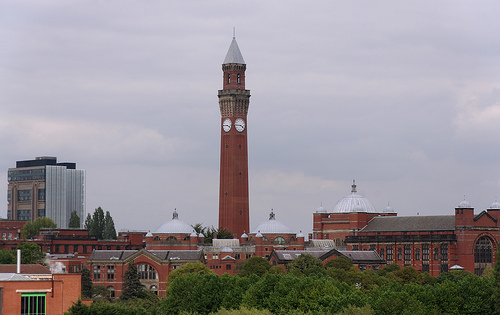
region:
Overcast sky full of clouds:
[0, 0, 499, 250]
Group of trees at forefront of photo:
[66, 248, 497, 314]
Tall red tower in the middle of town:
[203, 14, 265, 271]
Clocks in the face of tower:
[216, 112, 254, 139]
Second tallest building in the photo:
[0, 147, 95, 245]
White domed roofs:
[133, 178, 408, 243]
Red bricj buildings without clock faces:
[0, 198, 496, 313]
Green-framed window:
[16, 288, 51, 314]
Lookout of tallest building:
[219, 23, 249, 91]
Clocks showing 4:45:
[216, 113, 253, 138]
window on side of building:
[435, 243, 447, 261]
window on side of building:
[421, 243, 436, 266]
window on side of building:
[386, 246, 399, 264]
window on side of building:
[151, 267, 163, 280]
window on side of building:
[133, 265, 150, 282]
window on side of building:
[101, 265, 116, 278]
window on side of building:
[89, 261, 104, 278]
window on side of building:
[336, 240, 351, 246]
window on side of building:
[225, 263, 232, 273]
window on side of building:
[210, 262, 220, 270]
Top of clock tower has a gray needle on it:
[231, 24, 236, 36]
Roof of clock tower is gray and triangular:
[222, 38, 244, 64]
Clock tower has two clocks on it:
[221, 116, 247, 136]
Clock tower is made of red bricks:
[220, 132, 250, 237]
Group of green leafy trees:
[109, 261, 499, 313]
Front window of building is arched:
[473, 230, 497, 273]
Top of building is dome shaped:
[155, 209, 197, 234]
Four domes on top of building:
[314, 172, 395, 215]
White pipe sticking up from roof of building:
[15, 247, 22, 275]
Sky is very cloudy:
[2, 1, 498, 154]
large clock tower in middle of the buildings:
[213, 26, 253, 236]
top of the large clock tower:
[217, 24, 248, 89]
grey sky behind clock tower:
[3, 2, 498, 224]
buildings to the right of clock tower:
[250, 178, 498, 261]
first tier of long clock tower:
[215, 90, 250, 116]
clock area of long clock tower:
[219, 118, 247, 133]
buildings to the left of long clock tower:
[0, 207, 215, 314]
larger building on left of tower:
[6, 153, 88, 228]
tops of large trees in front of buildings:
[76, 259, 496, 314]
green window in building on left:
[19, 293, 44, 314]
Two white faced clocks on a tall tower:
[219, 116, 250, 134]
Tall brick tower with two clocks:
[215, 25, 257, 243]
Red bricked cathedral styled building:
[350, 198, 499, 278]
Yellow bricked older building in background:
[2, 155, 87, 228]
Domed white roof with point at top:
[306, 174, 396, 214]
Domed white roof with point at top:
[247, 206, 295, 233]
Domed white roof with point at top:
[152, 210, 199, 232]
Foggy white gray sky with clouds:
[1, 5, 214, 150]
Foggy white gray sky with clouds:
[253, 9, 496, 187]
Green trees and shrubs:
[90, 259, 498, 313]